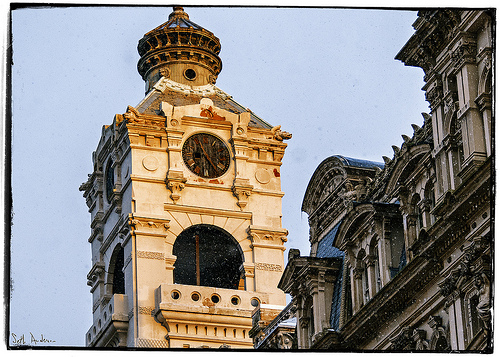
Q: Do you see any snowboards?
A: No, there are no snowboards.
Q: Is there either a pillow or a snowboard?
A: No, there are no snowboards or pillows.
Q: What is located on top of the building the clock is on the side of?
A: The dome is on top of the building.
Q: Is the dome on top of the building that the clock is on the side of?
A: Yes, the dome is on top of the building.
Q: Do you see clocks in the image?
A: Yes, there is a clock.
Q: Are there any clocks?
A: Yes, there is a clock.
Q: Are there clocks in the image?
A: Yes, there is a clock.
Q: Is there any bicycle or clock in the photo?
A: Yes, there is a clock.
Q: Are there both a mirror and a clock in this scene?
A: No, there is a clock but no mirrors.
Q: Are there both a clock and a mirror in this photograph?
A: No, there is a clock but no mirrors.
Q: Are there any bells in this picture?
A: No, there are no bells.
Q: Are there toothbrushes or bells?
A: No, there are no bells or toothbrushes.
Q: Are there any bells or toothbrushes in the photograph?
A: No, there are no bells or toothbrushes.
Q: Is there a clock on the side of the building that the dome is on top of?
A: Yes, there is a clock on the side of the building.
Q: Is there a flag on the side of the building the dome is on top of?
A: No, there is a clock on the side of the building.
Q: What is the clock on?
A: The clock is on the building.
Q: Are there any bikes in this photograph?
A: No, there are no bikes.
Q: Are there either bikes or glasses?
A: No, there are no bikes or glasses.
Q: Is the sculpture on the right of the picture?
A: Yes, the sculpture is on the right of the image.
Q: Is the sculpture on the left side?
A: No, the sculpture is on the right of the image.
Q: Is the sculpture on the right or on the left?
A: The sculpture is on the right of the image.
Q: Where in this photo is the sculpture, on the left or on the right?
A: The sculpture is on the right of the image.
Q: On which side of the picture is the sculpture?
A: The sculpture is on the right of the image.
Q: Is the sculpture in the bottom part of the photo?
A: Yes, the sculpture is in the bottom of the image.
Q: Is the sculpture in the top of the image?
A: No, the sculpture is in the bottom of the image.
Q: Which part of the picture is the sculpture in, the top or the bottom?
A: The sculpture is in the bottom of the image.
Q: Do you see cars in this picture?
A: No, there are no cars.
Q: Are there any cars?
A: No, there are no cars.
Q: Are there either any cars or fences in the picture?
A: No, there are no cars or fences.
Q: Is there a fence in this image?
A: No, there are no fences.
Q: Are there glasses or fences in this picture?
A: No, there are no fences or glasses.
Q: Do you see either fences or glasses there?
A: No, there are no fences or glasses.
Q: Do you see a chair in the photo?
A: No, there are no chairs.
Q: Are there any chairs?
A: No, there are no chairs.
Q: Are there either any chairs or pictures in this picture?
A: No, there are no chairs or pictures.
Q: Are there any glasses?
A: No, there are no glasses.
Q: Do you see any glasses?
A: No, there are no glasses.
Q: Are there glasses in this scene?
A: No, there are no glasses.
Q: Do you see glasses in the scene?
A: No, there are no glasses.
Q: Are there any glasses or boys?
A: No, there are no glasses or boys.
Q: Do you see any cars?
A: No, there are no cars.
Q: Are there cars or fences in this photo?
A: No, there are no cars or fences.